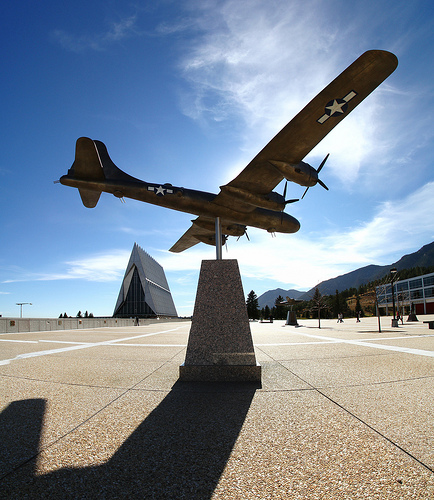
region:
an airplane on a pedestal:
[56, 48, 399, 255]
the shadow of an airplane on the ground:
[0, 380, 261, 496]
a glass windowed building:
[373, 276, 433, 313]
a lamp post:
[16, 299, 33, 317]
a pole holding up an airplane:
[213, 215, 223, 257]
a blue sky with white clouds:
[3, 1, 431, 317]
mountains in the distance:
[250, 239, 432, 306]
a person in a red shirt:
[394, 309, 403, 322]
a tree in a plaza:
[306, 288, 328, 329]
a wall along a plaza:
[1, 313, 181, 333]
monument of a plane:
[42, 48, 408, 275]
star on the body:
[140, 181, 174, 198]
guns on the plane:
[50, 173, 128, 207]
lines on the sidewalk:
[51, 372, 374, 457]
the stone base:
[179, 259, 263, 388]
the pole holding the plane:
[215, 211, 224, 263]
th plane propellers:
[280, 151, 335, 214]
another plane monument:
[270, 293, 309, 332]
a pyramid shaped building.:
[108, 236, 176, 320]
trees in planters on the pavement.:
[301, 276, 388, 334]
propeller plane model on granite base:
[58, 47, 400, 389]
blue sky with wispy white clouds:
[2, 17, 432, 318]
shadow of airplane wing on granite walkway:
[0, 394, 47, 498]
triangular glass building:
[112, 240, 180, 321]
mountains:
[247, 240, 432, 308]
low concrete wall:
[0, 316, 195, 333]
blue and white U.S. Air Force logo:
[314, 89, 358, 128]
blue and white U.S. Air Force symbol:
[145, 183, 174, 197]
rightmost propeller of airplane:
[301, 154, 332, 200]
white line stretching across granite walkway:
[1, 333, 430, 348]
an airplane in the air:
[52, 29, 433, 303]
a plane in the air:
[48, 65, 430, 330]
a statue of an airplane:
[40, 20, 429, 356]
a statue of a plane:
[53, 39, 400, 374]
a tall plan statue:
[38, 26, 414, 406]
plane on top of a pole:
[81, 109, 345, 397]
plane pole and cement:
[121, 135, 323, 407]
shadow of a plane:
[22, 303, 308, 494]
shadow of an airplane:
[47, 356, 291, 496]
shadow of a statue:
[47, 365, 241, 497]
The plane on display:
[47, 44, 399, 262]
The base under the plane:
[169, 255, 270, 385]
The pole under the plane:
[210, 217, 227, 264]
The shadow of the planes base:
[84, 372, 258, 499]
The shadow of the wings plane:
[0, 393, 54, 478]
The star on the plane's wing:
[322, 95, 348, 118]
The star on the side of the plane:
[153, 183, 169, 196]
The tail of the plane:
[50, 130, 117, 211]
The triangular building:
[106, 243, 184, 320]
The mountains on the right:
[239, 241, 433, 332]